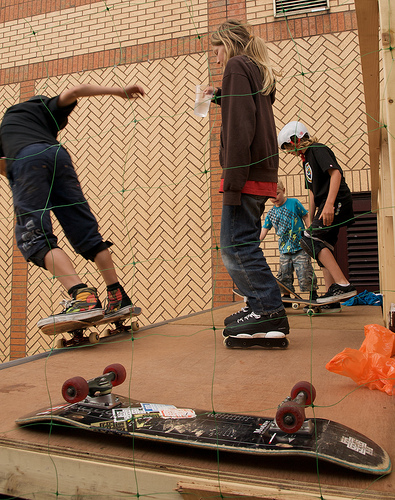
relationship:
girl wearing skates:
[198, 29, 303, 336] [220, 293, 289, 351]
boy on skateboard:
[2, 80, 144, 319] [38, 293, 143, 357]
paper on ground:
[328, 322, 394, 405] [5, 295, 394, 441]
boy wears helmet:
[278, 118, 358, 302] [278, 119, 306, 142]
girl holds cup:
[198, 29, 303, 336] [188, 76, 219, 125]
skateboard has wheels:
[16, 364, 388, 475] [62, 361, 318, 435]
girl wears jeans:
[198, 29, 303, 336] [220, 184, 284, 312]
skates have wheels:
[220, 293, 289, 351] [231, 335, 289, 347]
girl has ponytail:
[198, 29, 303, 336] [210, 18, 280, 93]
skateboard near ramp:
[38, 293, 143, 357] [4, 303, 233, 379]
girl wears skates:
[198, 29, 303, 336] [220, 293, 289, 351]